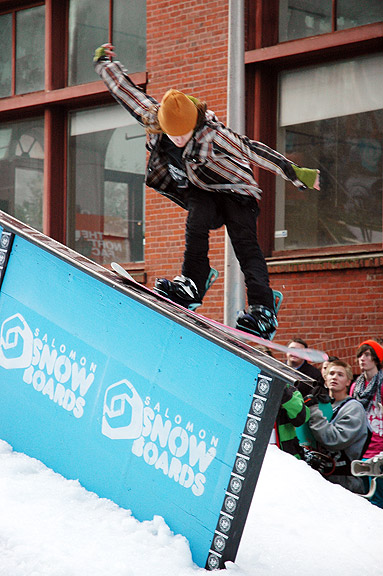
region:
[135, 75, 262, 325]
snowboarder sliding down sign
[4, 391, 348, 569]
thick white snow under sign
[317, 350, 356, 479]
blonde boy watching snow boarder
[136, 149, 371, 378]
bright red brick wall of building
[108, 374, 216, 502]
white lettering on blue sign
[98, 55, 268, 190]
plaid jacket on snowboarder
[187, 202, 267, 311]
black pants on snow boarder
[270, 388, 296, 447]
green and black sweater on observer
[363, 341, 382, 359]
red wool cap on observer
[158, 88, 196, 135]
man is wearing a hat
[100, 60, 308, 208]
white, black and orange jacket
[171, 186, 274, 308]
man is wearing black pants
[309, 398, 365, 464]
man is wearing a grey sweater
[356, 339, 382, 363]
man is wearing a head band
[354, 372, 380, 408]
man is wearing a scarf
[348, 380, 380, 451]
red and white shirt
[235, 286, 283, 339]
man has ski shoe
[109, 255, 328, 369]
man is on a snowboard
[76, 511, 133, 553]
a view of ice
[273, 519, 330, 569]
a view of snow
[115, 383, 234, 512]
text on the board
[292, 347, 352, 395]
face of the person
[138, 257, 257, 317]
shoe of the person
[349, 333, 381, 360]
hat of the person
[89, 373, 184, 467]
logo on the board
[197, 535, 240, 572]
marks on the side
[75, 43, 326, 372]
The man is on a snowboard.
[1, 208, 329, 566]
The snowboard is on a ramp.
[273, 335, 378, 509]
A crowd of people are watching the snowboarder.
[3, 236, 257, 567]
The sign on the snowboard is painted blue and white.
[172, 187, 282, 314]
The pants are black.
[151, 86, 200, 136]
The hat is orange.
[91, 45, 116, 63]
The gloves are green.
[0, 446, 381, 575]
The snow is white.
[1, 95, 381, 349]
The building in back is made of brick.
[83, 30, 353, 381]
A person on a snowboard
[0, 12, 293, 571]
A snowboarder grinding on a sign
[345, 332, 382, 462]
A person in a red cap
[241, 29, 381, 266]
A large glass window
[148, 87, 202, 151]
A brown cap on someone's head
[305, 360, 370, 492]
A person in a grey shirt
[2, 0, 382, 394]
A red brick building with several windows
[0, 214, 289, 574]
A blue Salomon Show Boards sign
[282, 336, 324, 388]
A partially obscured person in a black jacket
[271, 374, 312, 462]
A green and black striped shirt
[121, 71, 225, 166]
head of the person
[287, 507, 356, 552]
snow on the ground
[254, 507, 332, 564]
white snow on ground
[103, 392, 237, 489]
white words on sign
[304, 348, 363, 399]
head of a man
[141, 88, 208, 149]
orange hat on man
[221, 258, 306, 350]
foot of the man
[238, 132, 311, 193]
arm of the man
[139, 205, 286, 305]
pants on the man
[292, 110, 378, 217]
reflection in the window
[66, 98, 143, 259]
building has a window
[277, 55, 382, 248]
building has a window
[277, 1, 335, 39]
building has a window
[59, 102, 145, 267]
A window on a building.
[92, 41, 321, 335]
a boy on a snowboard